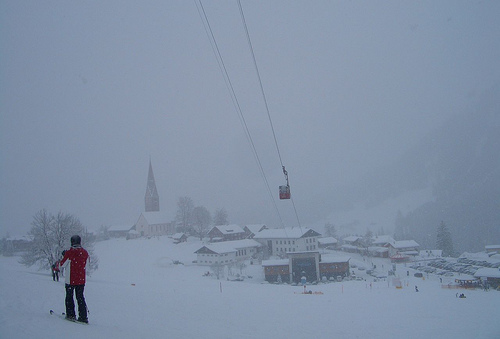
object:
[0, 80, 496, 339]
snow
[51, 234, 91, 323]
person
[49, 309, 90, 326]
skies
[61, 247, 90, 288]
jacket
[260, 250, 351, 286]
building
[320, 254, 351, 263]
roof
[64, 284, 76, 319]
legs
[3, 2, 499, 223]
sky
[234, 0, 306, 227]
power lines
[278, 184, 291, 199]
carriage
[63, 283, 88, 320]
pants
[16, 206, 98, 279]
tree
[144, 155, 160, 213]
church